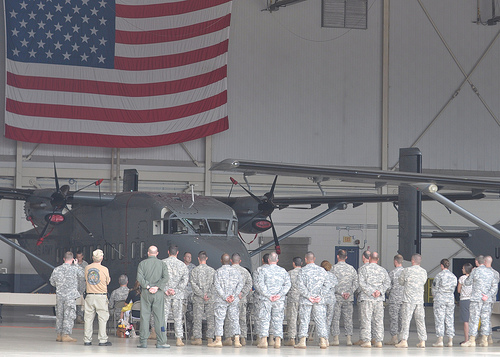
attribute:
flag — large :
[12, 10, 280, 162]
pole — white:
[379, 1, 391, 278]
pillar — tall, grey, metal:
[396, 146, 422, 256]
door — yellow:
[328, 236, 363, 311]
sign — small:
[343, 231, 353, 247]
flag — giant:
[2, 2, 230, 143]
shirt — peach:
[82, 262, 110, 292]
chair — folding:
[127, 298, 140, 321]